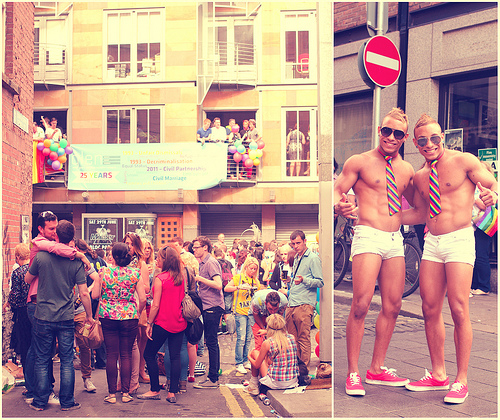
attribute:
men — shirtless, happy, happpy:
[339, 106, 472, 240]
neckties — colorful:
[383, 162, 447, 232]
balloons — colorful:
[41, 132, 76, 175]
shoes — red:
[344, 348, 465, 414]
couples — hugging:
[17, 203, 84, 288]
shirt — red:
[141, 273, 190, 335]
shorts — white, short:
[343, 220, 472, 280]